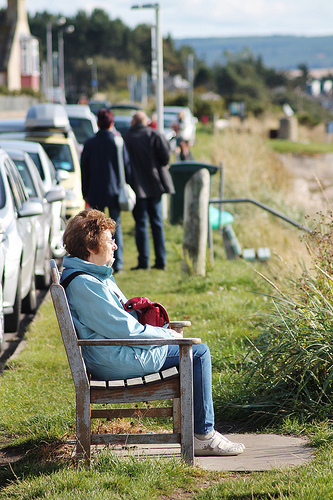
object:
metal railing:
[207, 194, 326, 265]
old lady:
[57, 206, 247, 458]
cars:
[0, 147, 50, 351]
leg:
[151, 343, 217, 432]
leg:
[107, 204, 124, 264]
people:
[80, 105, 133, 274]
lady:
[172, 107, 196, 160]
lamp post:
[154, 1, 165, 140]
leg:
[149, 201, 165, 259]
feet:
[193, 428, 246, 456]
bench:
[47, 257, 203, 473]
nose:
[112, 237, 119, 253]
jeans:
[162, 341, 216, 434]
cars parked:
[0, 142, 49, 346]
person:
[122, 109, 174, 272]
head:
[95, 108, 113, 133]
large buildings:
[0, 1, 42, 94]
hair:
[62, 205, 117, 263]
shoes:
[194, 430, 246, 455]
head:
[132, 111, 150, 133]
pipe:
[208, 195, 312, 266]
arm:
[69, 272, 180, 347]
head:
[65, 207, 119, 268]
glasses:
[97, 235, 115, 250]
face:
[101, 227, 118, 264]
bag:
[123, 293, 172, 331]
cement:
[67, 433, 320, 474]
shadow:
[0, 432, 66, 484]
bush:
[228, 258, 333, 434]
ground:
[0, 132, 333, 499]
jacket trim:
[60, 269, 97, 293]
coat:
[60, 255, 170, 381]